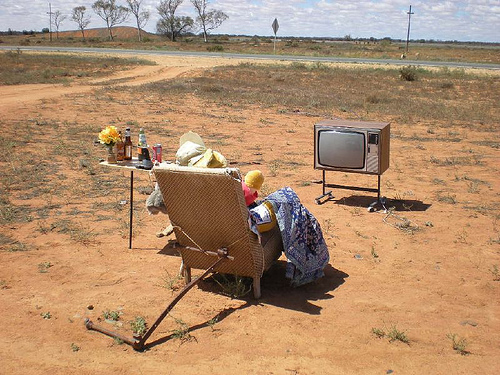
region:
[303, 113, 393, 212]
old tv sitting in the dirt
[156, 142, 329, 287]
chair with many items on it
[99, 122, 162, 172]
table with flowers and beer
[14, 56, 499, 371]
dirt with patches of grass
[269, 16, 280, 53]
square street sign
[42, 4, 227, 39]
row of leafless trees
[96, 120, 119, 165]
vase with yellow flowers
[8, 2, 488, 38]
bright light blue rippled water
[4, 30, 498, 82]
grey road running across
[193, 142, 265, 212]
stuffed animal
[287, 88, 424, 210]
a tv on the dirt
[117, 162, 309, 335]
a chair on the dirt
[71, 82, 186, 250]
a table on the dirt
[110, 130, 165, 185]
a bottle on the dirt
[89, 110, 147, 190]
a flower on a table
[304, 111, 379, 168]
the screen on a tv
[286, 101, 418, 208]
a tv outside in the dirt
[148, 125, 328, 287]
a brown chair outside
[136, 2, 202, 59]
a tree with no leaves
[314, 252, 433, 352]
dirt on the ground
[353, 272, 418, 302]
red clay on the ground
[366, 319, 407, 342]
small cluster of plant on the ground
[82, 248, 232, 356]
tree limb on back of chair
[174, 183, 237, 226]
light brown color on chair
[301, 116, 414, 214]
old fashioned television on ground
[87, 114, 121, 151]
yellow flower in vase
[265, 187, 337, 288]
blue and black fabric on chair's arm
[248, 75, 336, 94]
parched green grass on ground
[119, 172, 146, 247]
tall black leg on table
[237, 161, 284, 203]
small doll's face on chair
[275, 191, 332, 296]
blanket on the chair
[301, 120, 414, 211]
television alone in the dirt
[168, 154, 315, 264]
pile of items in the chair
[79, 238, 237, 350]
metal device for the chair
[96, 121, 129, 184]
flowers in a vase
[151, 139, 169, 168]
can of red soda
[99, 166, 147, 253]
tray on a black pole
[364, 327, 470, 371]
patches of grass sticking out of dirt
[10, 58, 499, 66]
a long road in front of tv